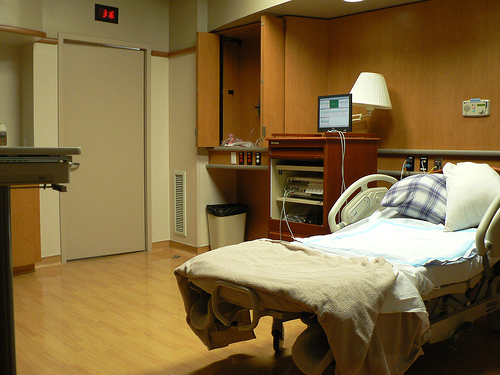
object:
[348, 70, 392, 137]
lamp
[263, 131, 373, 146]
shelf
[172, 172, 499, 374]
bed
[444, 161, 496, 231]
white pillow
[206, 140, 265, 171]
shelf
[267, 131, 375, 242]
dresser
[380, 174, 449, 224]
pillow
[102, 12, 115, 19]
number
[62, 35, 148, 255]
door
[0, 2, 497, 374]
room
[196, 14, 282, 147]
cabinet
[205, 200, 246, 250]
bag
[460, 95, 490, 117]
control box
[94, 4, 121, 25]
clock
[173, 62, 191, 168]
wall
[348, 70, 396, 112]
lamp shade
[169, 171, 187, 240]
vent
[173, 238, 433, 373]
blanket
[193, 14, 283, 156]
doors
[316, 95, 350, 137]
monitor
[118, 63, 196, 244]
wall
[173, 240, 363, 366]
foot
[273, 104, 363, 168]
shelf